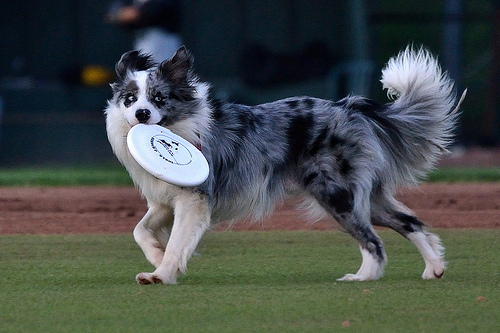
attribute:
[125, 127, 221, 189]
frisbee — white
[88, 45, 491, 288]
dog — black, white, gray black, running, gray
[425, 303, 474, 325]
grass — short, green, trimmed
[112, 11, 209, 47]
person — blurry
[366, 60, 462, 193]
tail — bushy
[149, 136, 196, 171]
logo — black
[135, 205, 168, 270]
leg — bent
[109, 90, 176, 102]
eyes — white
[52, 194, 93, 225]
dirt — clay, red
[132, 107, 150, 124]
nose — black, wet, shiny, small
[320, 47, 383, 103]
chair — white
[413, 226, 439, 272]
paw — white